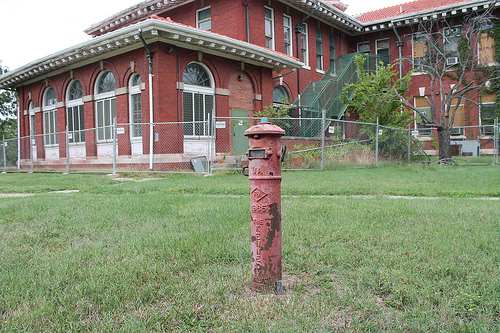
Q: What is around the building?
A: Fence.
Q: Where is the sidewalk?
A: In front of the building.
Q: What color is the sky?
A: White.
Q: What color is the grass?
A: Green.